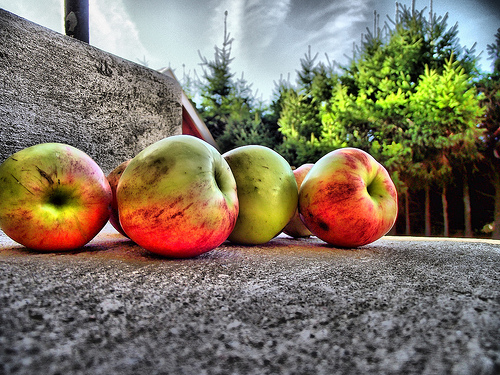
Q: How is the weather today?
A: It is cloudy.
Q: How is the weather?
A: It is cloudy.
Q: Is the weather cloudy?
A: Yes, it is cloudy.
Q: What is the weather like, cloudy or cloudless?
A: It is cloudy.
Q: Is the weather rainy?
A: No, it is cloudy.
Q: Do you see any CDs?
A: No, there are no cds.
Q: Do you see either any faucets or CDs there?
A: No, there are no CDs or faucets.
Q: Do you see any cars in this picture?
A: No, there are no cars.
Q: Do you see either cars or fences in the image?
A: No, there are no cars or fences.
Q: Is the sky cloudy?
A: Yes, the sky is cloudy.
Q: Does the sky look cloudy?
A: Yes, the sky is cloudy.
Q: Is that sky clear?
A: No, the sky is cloudy.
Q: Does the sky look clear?
A: No, the sky is cloudy.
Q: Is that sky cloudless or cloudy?
A: The sky is cloudy.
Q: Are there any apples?
A: Yes, there is an apple.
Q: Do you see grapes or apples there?
A: Yes, there is an apple.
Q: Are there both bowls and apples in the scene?
A: No, there is an apple but no bowls.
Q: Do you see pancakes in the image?
A: No, there are no pancakes.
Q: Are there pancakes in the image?
A: No, there are no pancakes.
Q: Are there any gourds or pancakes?
A: No, there are no pancakes or gourds.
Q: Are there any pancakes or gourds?
A: No, there are no pancakes or gourds.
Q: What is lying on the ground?
A: The apple is lying on the ground.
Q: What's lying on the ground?
A: The apple is lying on the ground.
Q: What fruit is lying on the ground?
A: The fruit is an apple.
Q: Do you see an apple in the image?
A: Yes, there is an apple.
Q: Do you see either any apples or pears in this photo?
A: Yes, there is an apple.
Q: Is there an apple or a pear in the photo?
A: Yes, there is an apple.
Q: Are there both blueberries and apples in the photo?
A: No, there is an apple but no blueberries.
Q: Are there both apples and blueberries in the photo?
A: No, there is an apple but no blueberries.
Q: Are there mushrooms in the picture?
A: No, there are no mushrooms.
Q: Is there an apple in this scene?
A: Yes, there are apples.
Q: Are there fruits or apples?
A: Yes, there are apples.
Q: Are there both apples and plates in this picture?
A: No, there are apples but no plates.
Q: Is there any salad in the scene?
A: No, there is no salad.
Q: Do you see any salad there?
A: No, there is no salad.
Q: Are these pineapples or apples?
A: These are apples.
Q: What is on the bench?
A: The apples are on the bench.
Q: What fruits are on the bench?
A: The fruits are apples.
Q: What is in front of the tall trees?
A: The apples are in front of the trees.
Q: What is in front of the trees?
A: The apples are in front of the trees.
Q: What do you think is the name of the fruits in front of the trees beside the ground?
A: The fruits are apples.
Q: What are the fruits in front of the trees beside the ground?
A: The fruits are apples.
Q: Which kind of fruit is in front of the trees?
A: The fruits are apples.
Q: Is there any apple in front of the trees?
A: Yes, there are apples in front of the trees.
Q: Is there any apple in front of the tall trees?
A: Yes, there are apples in front of the trees.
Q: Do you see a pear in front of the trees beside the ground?
A: No, there are apples in front of the trees.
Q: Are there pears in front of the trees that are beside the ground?
A: No, there are apples in front of the trees.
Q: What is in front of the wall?
A: The apples are in front of the wall.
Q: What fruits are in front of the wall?
A: The fruits are apples.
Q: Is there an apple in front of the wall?
A: Yes, there are apples in front of the wall.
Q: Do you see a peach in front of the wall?
A: No, there are apples in front of the wall.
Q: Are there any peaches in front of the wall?
A: No, there are apples in front of the wall.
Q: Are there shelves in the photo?
A: No, there are no shelves.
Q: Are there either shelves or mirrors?
A: No, there are no shelves or mirrors.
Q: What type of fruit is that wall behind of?
A: The wall is behind the apples.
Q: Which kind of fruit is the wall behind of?
A: The wall is behind the apples.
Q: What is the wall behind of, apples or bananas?
A: The wall is behind apples.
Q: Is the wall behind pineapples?
A: No, the wall is behind the apples.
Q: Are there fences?
A: No, there are no fences.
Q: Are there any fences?
A: No, there are no fences.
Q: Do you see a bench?
A: Yes, there is a bench.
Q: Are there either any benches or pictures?
A: Yes, there is a bench.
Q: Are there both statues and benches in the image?
A: No, there is a bench but no statues.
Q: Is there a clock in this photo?
A: No, there are no clocks.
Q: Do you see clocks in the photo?
A: No, there are no clocks.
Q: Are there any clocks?
A: No, there are no clocks.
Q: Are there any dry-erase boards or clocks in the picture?
A: No, there are no clocks or dry-erase boards.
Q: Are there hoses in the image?
A: No, there are no hoses.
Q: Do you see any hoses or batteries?
A: No, there are no hoses or batteries.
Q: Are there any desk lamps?
A: No, there are no desk lamps.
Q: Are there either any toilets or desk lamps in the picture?
A: No, there are no desk lamps or toilets.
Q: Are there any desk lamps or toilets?
A: No, there are no desk lamps or toilets.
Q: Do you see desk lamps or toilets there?
A: No, there are no desk lamps or toilets.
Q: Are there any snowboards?
A: No, there are no snowboards.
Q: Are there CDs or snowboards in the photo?
A: No, there are no snowboards or cds.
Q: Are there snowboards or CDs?
A: No, there are no snowboards or cds.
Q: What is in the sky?
A: The clouds are in the sky.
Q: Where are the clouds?
A: The clouds are in the sky.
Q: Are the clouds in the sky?
A: Yes, the clouds are in the sky.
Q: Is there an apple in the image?
A: Yes, there is an apple.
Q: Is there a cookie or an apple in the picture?
A: Yes, there is an apple.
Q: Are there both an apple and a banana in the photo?
A: No, there is an apple but no bananas.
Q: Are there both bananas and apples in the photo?
A: No, there is an apple but no bananas.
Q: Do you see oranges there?
A: No, there are no oranges.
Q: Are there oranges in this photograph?
A: No, there are no oranges.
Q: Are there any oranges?
A: No, there are no oranges.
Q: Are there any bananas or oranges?
A: No, there are no oranges or bananas.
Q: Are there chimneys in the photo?
A: No, there are no chimneys.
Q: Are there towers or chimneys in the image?
A: No, there are no chimneys or towers.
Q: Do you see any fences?
A: No, there are no fences.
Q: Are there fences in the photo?
A: No, there are no fences.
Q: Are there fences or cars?
A: No, there are no fences or cars.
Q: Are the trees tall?
A: Yes, the trees are tall.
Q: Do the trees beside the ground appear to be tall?
A: Yes, the trees are tall.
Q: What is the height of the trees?
A: The trees are tall.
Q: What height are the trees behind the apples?
A: The trees are tall.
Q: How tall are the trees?
A: The trees are tall.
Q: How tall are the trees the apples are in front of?
A: The trees are tall.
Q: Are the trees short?
A: No, the trees are tall.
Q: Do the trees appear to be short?
A: No, the trees are tall.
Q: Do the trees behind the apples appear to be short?
A: No, the trees are tall.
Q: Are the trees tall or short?
A: The trees are tall.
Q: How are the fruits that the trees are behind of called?
A: The fruits are apples.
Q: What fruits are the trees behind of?
A: The trees are behind the apples.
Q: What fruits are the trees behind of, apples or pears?
A: The trees are behind apples.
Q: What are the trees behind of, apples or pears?
A: The trees are behind apples.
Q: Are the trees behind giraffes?
A: No, the trees are behind the apples.